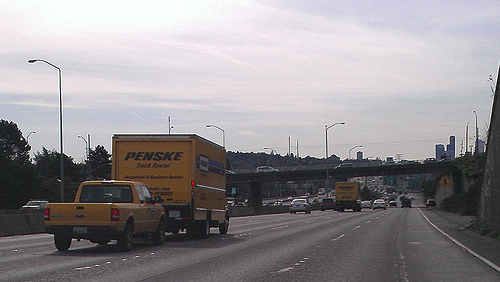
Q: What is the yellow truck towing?
A: Smaller truck.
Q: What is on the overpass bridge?
A: Cars.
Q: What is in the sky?
A: Clouds.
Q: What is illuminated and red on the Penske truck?
A: Brake lights.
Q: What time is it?
A: Afternoon.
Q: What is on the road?
A: A truck.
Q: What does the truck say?
A: Penske.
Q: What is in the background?
A: Buildings.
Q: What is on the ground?
A: White lines.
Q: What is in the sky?
A: Clouds.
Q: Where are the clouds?
A: In the sky.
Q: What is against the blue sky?
A: White clouds.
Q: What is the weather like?
A: Cloudy.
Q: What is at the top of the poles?
A: Lights.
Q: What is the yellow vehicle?
A: A pickup truck.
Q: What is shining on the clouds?
A: The sun.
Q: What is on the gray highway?
A: White stripes.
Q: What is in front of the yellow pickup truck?
A: A moving truck.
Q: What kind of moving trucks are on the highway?
A: Penske.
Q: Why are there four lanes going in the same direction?
A: A major highway.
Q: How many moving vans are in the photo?
A: Two.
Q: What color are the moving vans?
A: Yellow.